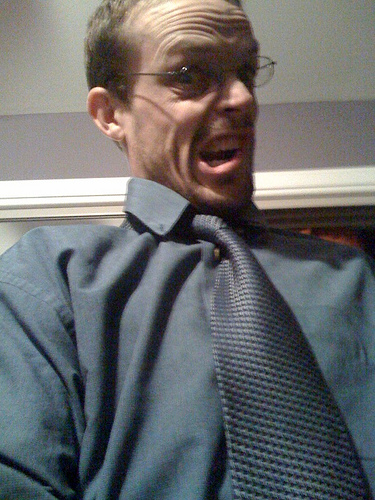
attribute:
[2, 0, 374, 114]
ceiling — gray, white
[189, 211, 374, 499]
tie — blue, black, blue patterned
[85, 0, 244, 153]
hair — brown, short, neat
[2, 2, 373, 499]
man — looking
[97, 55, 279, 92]
glasses — metal, thin, round, black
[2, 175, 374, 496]
shirt — blue, button down, light blue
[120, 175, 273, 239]
collar — high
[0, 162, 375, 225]
trim — white, wood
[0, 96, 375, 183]
wall — dark gray, gray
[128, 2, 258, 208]
face — funny, strange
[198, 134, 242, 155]
teeth — straight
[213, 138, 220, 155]
tooth — pointy